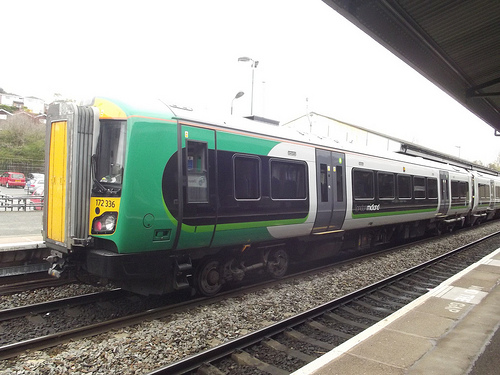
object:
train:
[44, 98, 498, 294]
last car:
[473, 161, 497, 223]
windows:
[270, 157, 309, 200]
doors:
[314, 148, 346, 235]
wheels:
[196, 256, 229, 297]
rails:
[1, 267, 160, 358]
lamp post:
[237, 56, 255, 115]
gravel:
[5, 315, 231, 374]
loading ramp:
[298, 268, 499, 368]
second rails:
[122, 228, 499, 374]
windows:
[94, 120, 125, 185]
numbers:
[112, 201, 116, 208]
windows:
[351, 165, 375, 202]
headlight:
[105, 215, 116, 231]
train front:
[40, 96, 155, 283]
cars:
[0, 171, 27, 189]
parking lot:
[0, 181, 42, 210]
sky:
[3, 2, 487, 136]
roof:
[313, 0, 500, 131]